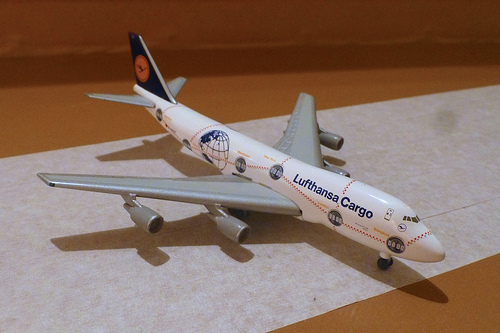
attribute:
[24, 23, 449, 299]
model — little, white, grey, jet, airplane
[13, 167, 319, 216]
wing — grey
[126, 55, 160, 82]
decal — orange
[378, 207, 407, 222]
decal — door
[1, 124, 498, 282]
surface — white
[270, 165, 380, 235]
logo — name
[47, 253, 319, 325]
paper — textured